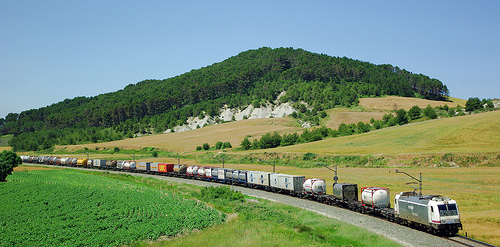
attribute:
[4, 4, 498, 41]
sky — clear, blue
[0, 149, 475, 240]
train — freight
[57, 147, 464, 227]
train — freight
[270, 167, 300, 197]
car — freight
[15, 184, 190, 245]
foliage — green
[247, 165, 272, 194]
car — freight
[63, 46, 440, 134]
trees — green